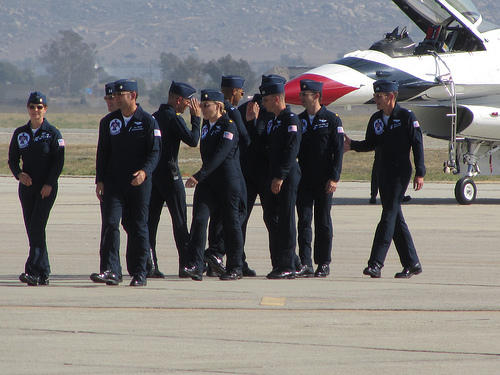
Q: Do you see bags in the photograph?
A: No, there are no bags.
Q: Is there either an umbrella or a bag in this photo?
A: No, there are no bags or umbrellas.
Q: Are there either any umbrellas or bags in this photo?
A: No, there are no bags or umbrellas.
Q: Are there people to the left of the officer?
A: Yes, there are people to the left of the officer.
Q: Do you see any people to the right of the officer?
A: No, the people are to the left of the officer.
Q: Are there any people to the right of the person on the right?
A: No, the people are to the left of the officer.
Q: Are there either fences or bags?
A: No, there are no fences or bags.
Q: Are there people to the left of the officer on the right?
A: Yes, there is a person to the left of the officer.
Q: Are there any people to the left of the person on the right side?
A: Yes, there is a person to the left of the officer.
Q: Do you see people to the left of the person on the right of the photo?
A: Yes, there is a person to the left of the officer.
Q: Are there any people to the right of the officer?
A: No, the person is to the left of the officer.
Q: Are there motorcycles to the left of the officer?
A: No, there is a person to the left of the officer.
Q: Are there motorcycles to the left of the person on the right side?
A: No, there is a person to the left of the officer.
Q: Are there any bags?
A: No, there are no bags.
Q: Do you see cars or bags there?
A: No, there are no bags or cars.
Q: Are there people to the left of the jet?
A: Yes, there is a person to the left of the jet.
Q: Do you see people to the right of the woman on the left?
A: Yes, there is a person to the right of the woman.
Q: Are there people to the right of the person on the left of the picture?
A: Yes, there is a person to the right of the woman.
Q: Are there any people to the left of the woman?
A: No, the person is to the right of the woman.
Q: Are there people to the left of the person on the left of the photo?
A: No, the person is to the right of the woman.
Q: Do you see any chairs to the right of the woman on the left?
A: No, there is a person to the right of the woman.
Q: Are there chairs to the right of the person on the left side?
A: No, there is a person to the right of the woman.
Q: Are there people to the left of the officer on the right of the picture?
A: Yes, there is a person to the left of the officer.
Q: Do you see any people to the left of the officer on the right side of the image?
A: Yes, there is a person to the left of the officer.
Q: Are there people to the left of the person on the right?
A: Yes, there is a person to the left of the officer.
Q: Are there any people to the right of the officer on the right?
A: No, the person is to the left of the officer.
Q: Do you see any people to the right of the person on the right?
A: No, the person is to the left of the officer.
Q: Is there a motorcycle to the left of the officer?
A: No, there is a person to the left of the officer.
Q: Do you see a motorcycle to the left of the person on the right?
A: No, there is a person to the left of the officer.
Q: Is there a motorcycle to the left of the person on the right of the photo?
A: No, there is a person to the left of the officer.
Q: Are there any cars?
A: No, there are no cars.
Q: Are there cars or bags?
A: No, there are no cars or bags.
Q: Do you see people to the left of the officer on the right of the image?
A: Yes, there is a person to the left of the officer.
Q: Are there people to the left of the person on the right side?
A: Yes, there is a person to the left of the officer.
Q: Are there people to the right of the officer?
A: No, the person is to the left of the officer.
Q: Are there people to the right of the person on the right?
A: No, the person is to the left of the officer.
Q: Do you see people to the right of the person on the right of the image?
A: No, the person is to the left of the officer.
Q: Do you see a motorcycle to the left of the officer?
A: No, there is a person to the left of the officer.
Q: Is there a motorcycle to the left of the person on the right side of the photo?
A: No, there is a person to the left of the officer.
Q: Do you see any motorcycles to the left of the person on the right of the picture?
A: No, there is a person to the left of the officer.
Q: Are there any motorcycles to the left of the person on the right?
A: No, there is a person to the left of the officer.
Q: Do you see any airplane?
A: Yes, there is an airplane.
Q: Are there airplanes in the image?
A: Yes, there is an airplane.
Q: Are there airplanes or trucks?
A: Yes, there is an airplane.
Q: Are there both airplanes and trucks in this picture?
A: No, there is an airplane but no trucks.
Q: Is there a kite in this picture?
A: No, there are no kites.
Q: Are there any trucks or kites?
A: No, there are no kites or trucks.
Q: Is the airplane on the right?
A: Yes, the airplane is on the right of the image.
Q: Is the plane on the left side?
A: No, the plane is on the right of the image.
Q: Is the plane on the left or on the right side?
A: The plane is on the right of the image.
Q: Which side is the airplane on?
A: The airplane is on the right of the image.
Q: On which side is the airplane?
A: The airplane is on the right of the image.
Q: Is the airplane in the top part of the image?
A: Yes, the airplane is in the top of the image.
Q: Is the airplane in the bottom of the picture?
A: No, the airplane is in the top of the image.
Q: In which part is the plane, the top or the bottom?
A: The plane is in the top of the image.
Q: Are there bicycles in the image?
A: No, there are no bicycles.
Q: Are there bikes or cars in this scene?
A: No, there are no bikes or cars.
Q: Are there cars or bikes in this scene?
A: No, there are no bikes or cars.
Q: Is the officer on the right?
A: Yes, the officer is on the right of the image.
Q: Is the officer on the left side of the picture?
A: No, the officer is on the right of the image.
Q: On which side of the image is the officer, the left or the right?
A: The officer is on the right of the image.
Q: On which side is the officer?
A: The officer is on the right of the image.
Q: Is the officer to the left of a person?
A: No, the officer is to the right of a person.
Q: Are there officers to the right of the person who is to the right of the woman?
A: Yes, there is an officer to the right of the person.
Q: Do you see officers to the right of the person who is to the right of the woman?
A: Yes, there is an officer to the right of the person.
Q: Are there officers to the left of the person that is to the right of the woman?
A: No, the officer is to the right of the person.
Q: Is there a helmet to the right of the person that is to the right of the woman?
A: No, there is an officer to the right of the person.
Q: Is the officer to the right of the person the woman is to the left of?
A: Yes, the officer is to the right of the person.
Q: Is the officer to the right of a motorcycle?
A: No, the officer is to the right of the person.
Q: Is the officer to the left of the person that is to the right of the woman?
A: No, the officer is to the right of the person.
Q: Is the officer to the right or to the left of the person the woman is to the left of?
A: The officer is to the right of the person.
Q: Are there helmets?
A: No, there are no helmets.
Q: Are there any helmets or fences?
A: No, there are no helmets or fences.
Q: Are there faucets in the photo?
A: No, there are no faucets.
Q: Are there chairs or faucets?
A: No, there are no faucets or chairs.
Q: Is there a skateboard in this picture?
A: No, there are no skateboards.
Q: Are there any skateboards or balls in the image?
A: No, there are no skateboards or balls.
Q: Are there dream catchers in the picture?
A: No, there are no dream catchers.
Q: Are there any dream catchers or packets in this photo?
A: No, there are no dream catchers or packets.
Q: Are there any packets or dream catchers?
A: No, there are no dream catchers or packets.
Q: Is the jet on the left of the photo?
A: No, the jet is on the right of the image.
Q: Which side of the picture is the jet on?
A: The jet is on the right of the image.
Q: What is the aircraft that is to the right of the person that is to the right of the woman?
A: The aircraft is a jet.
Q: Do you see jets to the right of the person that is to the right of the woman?
A: Yes, there is a jet to the right of the person.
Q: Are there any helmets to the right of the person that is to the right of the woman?
A: No, there is a jet to the right of the person.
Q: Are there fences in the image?
A: No, there are no fences.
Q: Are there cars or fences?
A: No, there are no fences or cars.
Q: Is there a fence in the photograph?
A: No, there are no fences.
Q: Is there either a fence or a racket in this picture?
A: No, there are no fences or rackets.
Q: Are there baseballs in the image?
A: No, there are no baseballs.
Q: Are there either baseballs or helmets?
A: No, there are no baseballs or helmets.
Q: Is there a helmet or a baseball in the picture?
A: No, there are no baseballs or helmets.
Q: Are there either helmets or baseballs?
A: No, there are no baseballs or helmets.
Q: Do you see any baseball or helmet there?
A: No, there are no baseballs or helmets.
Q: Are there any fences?
A: No, there are no fences.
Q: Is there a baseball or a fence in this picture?
A: No, there are no fences or baseballs.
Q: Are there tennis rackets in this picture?
A: No, there are no tennis rackets.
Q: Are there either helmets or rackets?
A: No, there are no rackets or helmets.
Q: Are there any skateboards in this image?
A: No, there are no skateboards.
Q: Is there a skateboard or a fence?
A: No, there are no skateboards or fences.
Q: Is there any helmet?
A: No, there are no helmets.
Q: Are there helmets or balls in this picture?
A: No, there are no helmets or balls.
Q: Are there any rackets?
A: No, there are no rackets.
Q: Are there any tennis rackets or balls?
A: No, there are no tennis rackets or balls.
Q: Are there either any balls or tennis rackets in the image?
A: No, there are no tennis rackets or balls.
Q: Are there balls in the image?
A: No, there are no balls.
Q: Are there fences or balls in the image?
A: No, there are no balls or fences.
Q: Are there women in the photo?
A: Yes, there is a woman.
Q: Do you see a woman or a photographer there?
A: Yes, there is a woman.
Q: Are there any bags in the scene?
A: No, there are no bags.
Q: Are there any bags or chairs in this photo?
A: No, there are no bags or chairs.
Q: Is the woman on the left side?
A: Yes, the woman is on the left of the image.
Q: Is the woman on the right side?
A: No, the woman is on the left of the image.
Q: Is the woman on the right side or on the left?
A: The woman is on the left of the image.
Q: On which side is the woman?
A: The woman is on the left of the image.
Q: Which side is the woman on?
A: The woman is on the left of the image.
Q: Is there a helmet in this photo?
A: No, there are no helmets.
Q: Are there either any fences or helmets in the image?
A: No, there are no helmets or fences.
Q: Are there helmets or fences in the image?
A: No, there are no helmets or fences.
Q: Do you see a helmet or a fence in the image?
A: No, there are no helmets or fences.